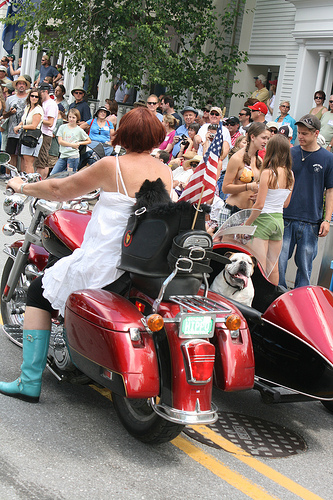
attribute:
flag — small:
[171, 121, 224, 204]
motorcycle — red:
[1, 173, 255, 445]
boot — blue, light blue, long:
[1, 328, 54, 404]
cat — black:
[129, 177, 176, 218]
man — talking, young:
[280, 113, 332, 289]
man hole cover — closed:
[180, 410, 311, 459]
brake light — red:
[145, 314, 166, 332]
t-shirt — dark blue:
[285, 147, 332, 226]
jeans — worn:
[279, 216, 319, 290]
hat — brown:
[295, 114, 326, 131]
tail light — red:
[223, 313, 246, 337]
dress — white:
[42, 154, 181, 319]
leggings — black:
[24, 273, 56, 313]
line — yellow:
[187, 420, 331, 499]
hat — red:
[247, 101, 269, 116]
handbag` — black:
[16, 125, 43, 150]